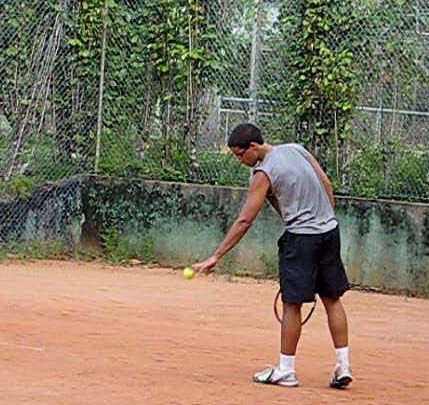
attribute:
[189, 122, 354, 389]
man — playing, young, black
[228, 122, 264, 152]
hair — black, dark, short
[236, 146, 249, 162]
glasses — dark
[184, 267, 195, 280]
tennis ball — yellow, green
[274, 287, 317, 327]
tennis racquet — held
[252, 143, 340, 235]
pullover — sleeveless, gray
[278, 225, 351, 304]
shorts — dark, black, blue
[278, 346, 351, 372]
socks — men's, white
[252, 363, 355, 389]
tennis shoes — white, men's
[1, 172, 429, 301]
wall — low, concrete, stone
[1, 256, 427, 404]
tennis court — dirt, red clay, clay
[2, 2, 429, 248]
fence — present, tall, metal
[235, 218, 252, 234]
elbow — wrinkly